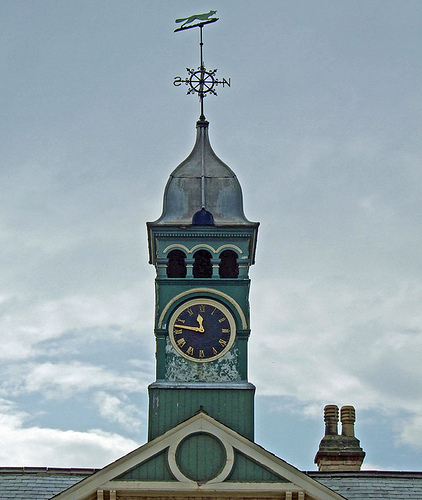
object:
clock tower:
[145, 114, 261, 442]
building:
[0, 113, 420, 498]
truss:
[44, 404, 347, 499]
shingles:
[2, 474, 54, 490]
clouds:
[0, 284, 156, 471]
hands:
[174, 324, 205, 334]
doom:
[145, 114, 259, 225]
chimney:
[314, 404, 367, 472]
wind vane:
[168, 4, 235, 122]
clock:
[167, 297, 237, 364]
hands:
[196, 314, 205, 334]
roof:
[0, 465, 419, 499]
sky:
[0, 0, 421, 472]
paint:
[164, 335, 241, 382]